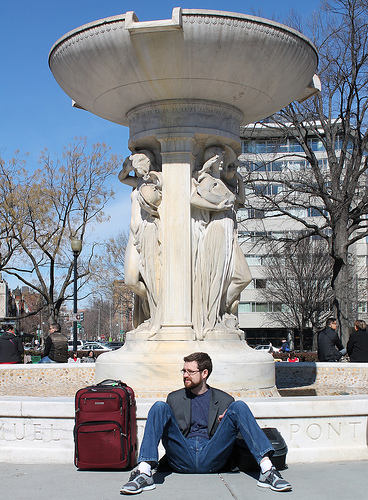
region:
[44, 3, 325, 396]
A cement statue in the middle of a city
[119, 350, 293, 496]
A man sitting on the ground by a statue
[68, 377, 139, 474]
A red piece of luggage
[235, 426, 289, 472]
A black piece of luggage on the ground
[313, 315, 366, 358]
Two people sitting around a cement ledge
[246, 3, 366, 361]
A leafless tree in the middle of a city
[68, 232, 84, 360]
A black street light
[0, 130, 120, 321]
A tree with green leaves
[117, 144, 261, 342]
A statue of two people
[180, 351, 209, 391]
A man wearing eye glasses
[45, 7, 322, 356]
A fountain sculpture in the city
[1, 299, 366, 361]
A busy city street scene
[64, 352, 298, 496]
A traveler sitting by a fountain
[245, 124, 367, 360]
An apartment building on a busy street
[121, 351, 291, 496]
A man waiting by a fountain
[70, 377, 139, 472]
A red suitcase by a fountain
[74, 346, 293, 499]
A traveler waiting by a fountain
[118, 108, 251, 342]
The sculpture above a fountain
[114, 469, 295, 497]
Sneakers on a city sidewalk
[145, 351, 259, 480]
A sitting man wearing glases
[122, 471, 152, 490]
tennis shoe on man's foot.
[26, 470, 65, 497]
concrete sidewalk near statue.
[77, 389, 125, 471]
maroon suitcase near man.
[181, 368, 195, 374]
glasses on man's face.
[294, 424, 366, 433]
inscription on statue perimeter.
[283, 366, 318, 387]
shadow near the statue.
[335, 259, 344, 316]
trunk of the tree.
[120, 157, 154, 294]
concrete statue of a human.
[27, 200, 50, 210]
leaves on the tree.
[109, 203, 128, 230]
cloud in the sky.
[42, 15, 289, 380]
a white stone statue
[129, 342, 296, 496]
a man is sitting on the ground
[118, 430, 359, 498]
the man's pants are highwaters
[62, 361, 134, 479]
the man has a maroon colored suitcase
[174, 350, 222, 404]
the man has brown hair and glasses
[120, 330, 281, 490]
man is in front of a fountain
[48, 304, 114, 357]
cars on the road in the background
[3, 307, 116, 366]
people sitting on the pool wall around the fountain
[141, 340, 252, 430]
the man has a brown beard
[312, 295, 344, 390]
guy wearing a black jacket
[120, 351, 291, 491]
a man sitting on ground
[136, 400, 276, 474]
a pair of blue jeans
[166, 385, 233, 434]
a grey man's jacket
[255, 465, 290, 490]
a grey tennis shoe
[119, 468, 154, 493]
a grey tennis shoe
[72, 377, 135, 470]
a maroon piece of luggage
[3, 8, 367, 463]
a sculptural water fountain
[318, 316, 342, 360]
a person sitting on fountain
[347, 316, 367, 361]
a person sitting on fountain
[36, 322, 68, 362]
a person sitting on fountain